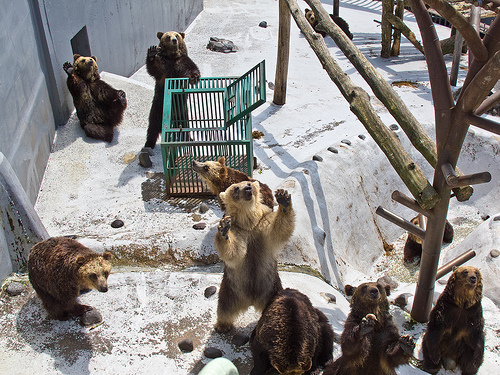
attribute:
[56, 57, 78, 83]
foot — dark, brown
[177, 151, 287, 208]
bear — juvenile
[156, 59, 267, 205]
cage — large, green, empty, metal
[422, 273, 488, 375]
bear sitting — brown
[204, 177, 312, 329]
light brown bear — light brown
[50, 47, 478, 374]
coloured bears — many coloured, hearty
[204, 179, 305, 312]
tannish bear — large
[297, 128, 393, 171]
dark round rocks — large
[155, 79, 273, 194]
open cage visible — green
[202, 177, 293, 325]
standing on two legs — bear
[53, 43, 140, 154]
sitting down — bear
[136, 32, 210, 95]
holding cage — bear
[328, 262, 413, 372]
down and waving — bear